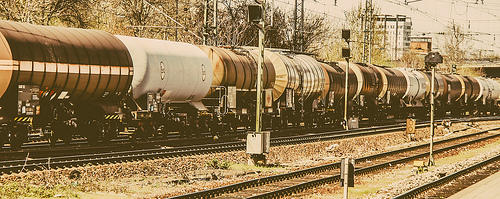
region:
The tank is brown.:
[0, 20, 132, 106]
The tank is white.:
[121, 33, 216, 106]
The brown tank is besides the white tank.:
[1, 20, 213, 99]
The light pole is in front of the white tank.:
[129, 2, 285, 164]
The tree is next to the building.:
[364, 5, 411, 67]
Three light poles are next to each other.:
[237, 0, 465, 168]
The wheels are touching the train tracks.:
[5, 113, 154, 175]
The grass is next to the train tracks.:
[220, 155, 307, 197]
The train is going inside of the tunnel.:
[440, 39, 498, 126]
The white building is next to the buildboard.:
[374, 9, 434, 70]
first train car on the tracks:
[0, 16, 136, 150]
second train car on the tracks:
[113, 29, 219, 142]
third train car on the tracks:
[199, 43, 276, 124]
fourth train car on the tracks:
[266, 47, 333, 127]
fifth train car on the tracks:
[316, 57, 358, 107]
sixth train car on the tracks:
[343, 55, 384, 113]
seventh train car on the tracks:
[375, 60, 406, 111]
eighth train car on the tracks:
[404, 62, 431, 106]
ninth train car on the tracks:
[426, 66, 446, 106]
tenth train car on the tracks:
[445, 72, 462, 107]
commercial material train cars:
[2, 13, 499, 150]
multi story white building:
[360, 7, 415, 64]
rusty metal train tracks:
[2, 111, 499, 196]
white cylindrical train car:
[111, 26, 213, 145]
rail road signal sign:
[238, 2, 273, 167]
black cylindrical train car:
[0, 13, 131, 149]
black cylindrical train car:
[316, 53, 356, 128]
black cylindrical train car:
[338, 54, 387, 126]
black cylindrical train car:
[368, 60, 408, 118]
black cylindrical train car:
[195, 40, 275, 137]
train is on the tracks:
[0, 20, 498, 170]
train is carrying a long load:
[1, 15, 498, 137]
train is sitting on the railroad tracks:
[1, 20, 499, 145]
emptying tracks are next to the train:
[0, 15, 499, 197]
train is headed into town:
[0, 15, 499, 147]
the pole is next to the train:
[242, 0, 272, 160]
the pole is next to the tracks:
[240, 0, 272, 167]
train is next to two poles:
[0, 0, 360, 154]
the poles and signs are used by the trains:
[244, 2, 446, 197]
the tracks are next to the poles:
[3, 127, 496, 195]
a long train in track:
[31, 28, 491, 113]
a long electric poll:
[327, 35, 354, 196]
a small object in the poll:
[231, 132, 291, 164]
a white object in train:
[107, 15, 224, 130]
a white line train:
[21, 56, 146, 88]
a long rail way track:
[262, 116, 491, 197]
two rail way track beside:
[236, 138, 489, 195]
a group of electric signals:
[218, 26, 498, 138]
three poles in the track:
[207, 47, 495, 184]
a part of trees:
[112, 10, 468, 60]